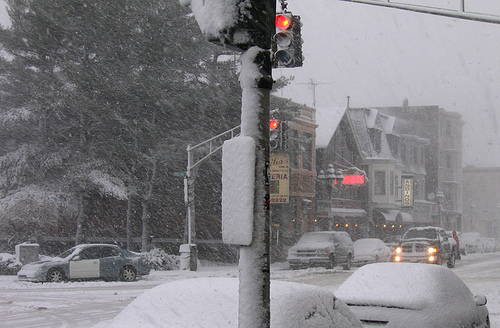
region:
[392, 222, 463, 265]
A truck driving down a snowy road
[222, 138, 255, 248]
a snow covered street sign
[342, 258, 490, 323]
a parked car covered in snow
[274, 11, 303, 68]
a traffic light on red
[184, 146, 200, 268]
a pole holding a traffic light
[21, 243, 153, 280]
a gray car with one white door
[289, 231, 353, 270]
an SUV parked on a snowy road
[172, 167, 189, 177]
A street sign on a pole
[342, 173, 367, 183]
A red lit business sign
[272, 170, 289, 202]
A white sign with black lettering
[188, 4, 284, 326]
a metal pole covered in snow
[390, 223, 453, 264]
truck driving with headlights on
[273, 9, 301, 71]
a traffic signal lit up red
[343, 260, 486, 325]
car completely covered in white snow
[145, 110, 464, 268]
row of buildings along street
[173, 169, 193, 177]
green and white road sign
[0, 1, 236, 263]
large leafy trees along street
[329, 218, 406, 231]
lights running along side of building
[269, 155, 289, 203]
white and red pizzeria sign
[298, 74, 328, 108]
television antenna on top of building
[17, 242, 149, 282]
the car on the road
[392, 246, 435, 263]
the lights on the truck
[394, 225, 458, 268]
the truck on the road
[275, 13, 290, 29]
the red street light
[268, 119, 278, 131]
the red street light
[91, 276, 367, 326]
the park car covered in snow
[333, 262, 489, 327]
the park car covered in snow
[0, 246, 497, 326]
the snow covered the road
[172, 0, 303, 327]
the snow on the street poles, lights and signs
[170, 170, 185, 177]
the green street sign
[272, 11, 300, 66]
Stoplight that is on red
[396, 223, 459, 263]
A truck driving on a road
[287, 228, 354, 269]
SUV parked in the snow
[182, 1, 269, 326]
A metal pole with snow on it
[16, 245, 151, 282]
A car driving along in the snow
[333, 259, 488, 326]
A car snowed in that is parked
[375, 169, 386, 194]
Window in a building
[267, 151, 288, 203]
Sign on a building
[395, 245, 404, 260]
Headlights shining from a vehicle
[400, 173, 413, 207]
A banner on a building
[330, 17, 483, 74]
this is the sky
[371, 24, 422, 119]
the sky is blue in color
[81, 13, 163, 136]
this is a tree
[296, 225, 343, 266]
this is a car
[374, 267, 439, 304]
this is a snow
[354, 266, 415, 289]
the snow is white in color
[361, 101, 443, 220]
this is a building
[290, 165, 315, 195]
this is the wall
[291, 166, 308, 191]
the wall is brown in color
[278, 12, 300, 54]
this is the traffic light